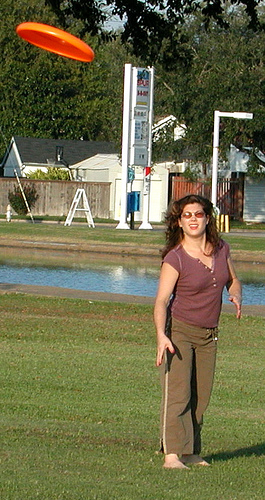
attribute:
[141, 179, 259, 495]
woman — barefoot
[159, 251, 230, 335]
shirt — brown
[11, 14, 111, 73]
frisbee — orange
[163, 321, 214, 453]
pants — brown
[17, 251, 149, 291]
water — calm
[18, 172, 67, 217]
fence — wooden